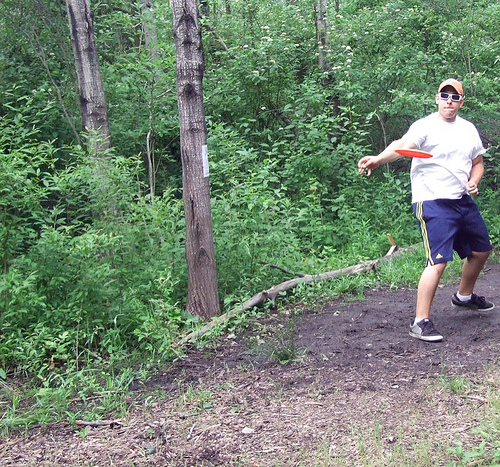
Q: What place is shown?
A: It is a path.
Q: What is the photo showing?
A: It is showing a path.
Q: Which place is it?
A: It is a path.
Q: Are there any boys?
A: No, there are no boys.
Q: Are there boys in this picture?
A: No, there are no boys.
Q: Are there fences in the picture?
A: No, there are no fences.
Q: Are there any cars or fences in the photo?
A: No, there are no fences or cars.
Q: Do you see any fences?
A: No, there are no fences.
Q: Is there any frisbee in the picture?
A: Yes, there is a frisbee.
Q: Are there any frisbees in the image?
A: Yes, there is a frisbee.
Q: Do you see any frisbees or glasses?
A: Yes, there is a frisbee.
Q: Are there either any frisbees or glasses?
A: Yes, there is a frisbee.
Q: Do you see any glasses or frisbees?
A: Yes, there is a frisbee.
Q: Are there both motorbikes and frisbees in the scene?
A: No, there is a frisbee but no motorcycles.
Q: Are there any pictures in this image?
A: No, there are no pictures.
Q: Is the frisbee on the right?
A: Yes, the frisbee is on the right of the image.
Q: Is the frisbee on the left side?
A: No, the frisbee is on the right of the image.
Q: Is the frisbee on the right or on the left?
A: The frisbee is on the right of the image.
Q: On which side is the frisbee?
A: The frisbee is on the right of the image.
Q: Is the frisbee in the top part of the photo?
A: Yes, the frisbee is in the top of the image.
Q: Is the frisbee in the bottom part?
A: No, the frisbee is in the top of the image.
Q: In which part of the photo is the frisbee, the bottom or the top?
A: The frisbee is in the top of the image.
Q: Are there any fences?
A: No, there are no fences.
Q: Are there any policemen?
A: No, there are no policemen.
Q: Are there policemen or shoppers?
A: No, there are no policemen or shoppers.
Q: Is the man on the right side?
A: Yes, the man is on the right of the image.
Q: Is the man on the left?
A: No, the man is on the right of the image.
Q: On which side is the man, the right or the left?
A: The man is on the right of the image.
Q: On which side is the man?
A: The man is on the right of the image.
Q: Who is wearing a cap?
A: The man is wearing a cap.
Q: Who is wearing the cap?
A: The man is wearing a cap.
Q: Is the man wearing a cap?
A: Yes, the man is wearing a cap.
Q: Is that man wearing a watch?
A: No, the man is wearing a cap.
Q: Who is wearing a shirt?
A: The man is wearing a shirt.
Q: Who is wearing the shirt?
A: The man is wearing a shirt.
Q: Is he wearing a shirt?
A: Yes, the man is wearing a shirt.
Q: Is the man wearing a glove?
A: No, the man is wearing a shirt.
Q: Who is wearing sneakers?
A: The man is wearing sneakers.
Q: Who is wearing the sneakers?
A: The man is wearing sneakers.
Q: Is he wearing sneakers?
A: Yes, the man is wearing sneakers.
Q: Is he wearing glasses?
A: No, the man is wearing sneakers.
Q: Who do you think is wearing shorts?
A: The man is wearing shorts.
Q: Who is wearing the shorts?
A: The man is wearing shorts.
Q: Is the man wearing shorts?
A: Yes, the man is wearing shorts.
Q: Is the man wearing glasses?
A: No, the man is wearing shorts.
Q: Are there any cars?
A: No, there are no cars.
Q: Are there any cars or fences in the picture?
A: No, there are no cars or fences.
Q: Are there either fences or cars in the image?
A: No, there are no cars or fences.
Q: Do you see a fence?
A: No, there are no fences.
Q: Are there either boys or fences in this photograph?
A: No, there are no fences or boys.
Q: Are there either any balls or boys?
A: No, there are no boys or balls.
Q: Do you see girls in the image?
A: No, there are no girls.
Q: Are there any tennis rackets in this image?
A: No, there are no tennis rackets.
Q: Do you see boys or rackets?
A: No, there are no rackets or boys.